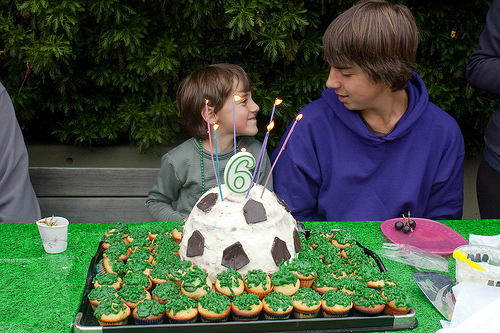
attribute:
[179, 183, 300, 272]
cake — ball, dome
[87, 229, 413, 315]
cupcakes — green, decorated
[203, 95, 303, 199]
candles — thin, long, tall, lit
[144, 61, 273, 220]
boy — grinning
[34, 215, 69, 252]
cup — small, disposable, paper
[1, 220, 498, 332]
table — grass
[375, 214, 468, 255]
plate — pink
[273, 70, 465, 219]
clothing — blue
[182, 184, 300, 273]
frosting — white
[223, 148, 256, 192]
candle — number, white, lit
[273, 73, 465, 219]
shirt — hooded, purple, blue, hoodie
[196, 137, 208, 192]
necklace — green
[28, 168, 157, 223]
bench — wood, wooden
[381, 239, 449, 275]
bag — plastic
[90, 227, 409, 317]
frosting — green